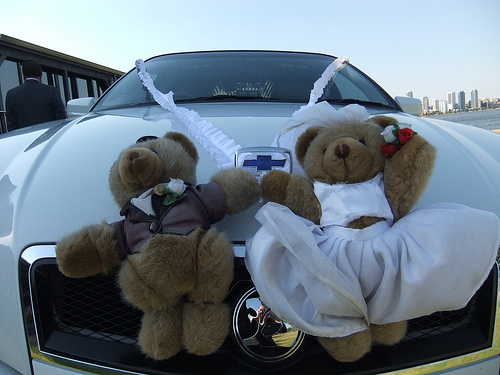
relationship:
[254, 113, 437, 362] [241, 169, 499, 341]
stuffed bear in dress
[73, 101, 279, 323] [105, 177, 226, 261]
bear in tuxedo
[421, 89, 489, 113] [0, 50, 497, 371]
buildings behind car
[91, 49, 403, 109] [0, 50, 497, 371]
windshield of car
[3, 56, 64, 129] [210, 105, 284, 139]
man standing next to car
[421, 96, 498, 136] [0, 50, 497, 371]
body water behind car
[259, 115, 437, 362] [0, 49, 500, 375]
stuffed bear attached to car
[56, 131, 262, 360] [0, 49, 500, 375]
bear attached to car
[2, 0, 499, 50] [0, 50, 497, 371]
sky above car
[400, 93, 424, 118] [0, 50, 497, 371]
mirror on side car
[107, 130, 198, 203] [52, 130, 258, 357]
head of bear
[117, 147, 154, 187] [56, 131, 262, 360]
mouth of bear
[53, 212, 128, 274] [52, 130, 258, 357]
arm of bear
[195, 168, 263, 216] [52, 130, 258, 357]
arm of bear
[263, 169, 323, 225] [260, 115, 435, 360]
arm of bear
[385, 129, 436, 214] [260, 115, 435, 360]
arm of bear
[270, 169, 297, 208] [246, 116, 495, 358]
arm of teddy bear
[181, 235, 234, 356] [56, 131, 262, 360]
leg of bear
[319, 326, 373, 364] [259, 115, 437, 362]
leg of stuffed bear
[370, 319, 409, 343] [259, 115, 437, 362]
leg of stuffed bear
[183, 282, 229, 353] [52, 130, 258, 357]
leg of bear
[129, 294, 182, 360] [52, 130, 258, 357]
leg of bear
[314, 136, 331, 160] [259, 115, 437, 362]
eye of stuffed bear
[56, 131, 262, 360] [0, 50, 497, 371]
bear on front of car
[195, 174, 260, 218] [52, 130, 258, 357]
arm of a bear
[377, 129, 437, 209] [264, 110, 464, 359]
arm of a teddy bear